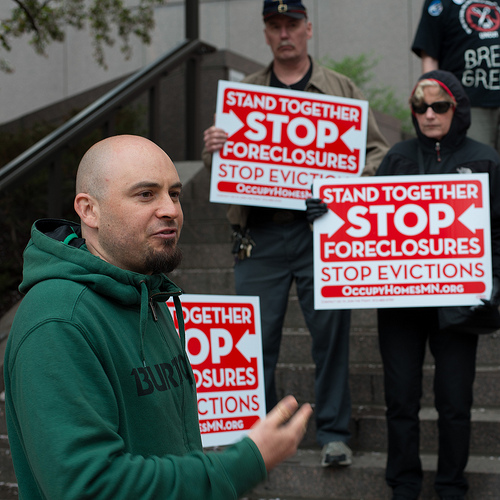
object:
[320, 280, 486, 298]
lettering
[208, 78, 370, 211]
red sign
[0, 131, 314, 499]
male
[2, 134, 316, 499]
person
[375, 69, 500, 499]
person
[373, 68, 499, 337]
jacket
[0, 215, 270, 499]
hoodie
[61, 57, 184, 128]
gray railing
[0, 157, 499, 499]
stairs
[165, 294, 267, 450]
sign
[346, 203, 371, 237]
letter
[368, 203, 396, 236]
letter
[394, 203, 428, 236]
letter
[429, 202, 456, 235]
letter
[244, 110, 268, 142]
letter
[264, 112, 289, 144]
letter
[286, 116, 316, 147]
letter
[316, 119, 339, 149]
letter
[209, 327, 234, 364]
letter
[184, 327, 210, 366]
letter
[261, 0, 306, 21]
hat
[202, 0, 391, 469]
man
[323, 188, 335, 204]
letter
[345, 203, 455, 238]
lettering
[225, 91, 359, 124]
white lettering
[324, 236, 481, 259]
white lettering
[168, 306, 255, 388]
white lettering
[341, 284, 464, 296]
white lettering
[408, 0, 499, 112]
shirt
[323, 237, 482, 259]
lettering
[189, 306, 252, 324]
lettering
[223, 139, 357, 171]
lettering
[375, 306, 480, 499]
black pants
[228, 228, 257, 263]
keys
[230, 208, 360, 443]
pants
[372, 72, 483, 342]
badsentese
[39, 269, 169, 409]
sweater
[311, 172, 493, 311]
sign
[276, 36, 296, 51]
moustache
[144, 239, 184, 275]
goatee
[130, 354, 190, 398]
letters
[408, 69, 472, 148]
hood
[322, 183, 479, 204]
lettering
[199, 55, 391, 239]
jacket